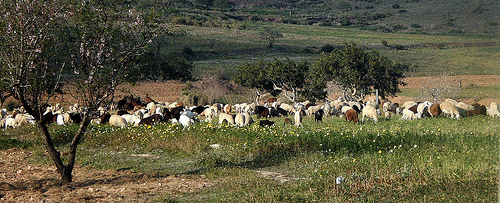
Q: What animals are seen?
A: Sheep.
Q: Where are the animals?
A: Field.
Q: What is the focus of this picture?
A: Animals.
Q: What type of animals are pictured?
A: Cattle.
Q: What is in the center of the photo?
A: Row of trees.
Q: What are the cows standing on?
A: Grass.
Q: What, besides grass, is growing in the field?
A: Flowers.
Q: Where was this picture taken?
A: In a field.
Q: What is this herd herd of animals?
A: Grass.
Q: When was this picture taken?
A: During the day hours.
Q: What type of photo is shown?
A: Panorama.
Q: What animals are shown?
A: Cows.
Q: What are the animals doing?
A: Eating.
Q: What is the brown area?
A: Dirt.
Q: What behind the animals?
A: Hills.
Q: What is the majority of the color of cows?
A: White.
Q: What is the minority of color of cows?
A: Brown.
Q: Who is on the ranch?
A: Cattle.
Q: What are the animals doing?
A: Grazing.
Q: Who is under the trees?
A: Cattle.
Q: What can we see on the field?
A: A herd of cattle.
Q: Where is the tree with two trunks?
A: On the left.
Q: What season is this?
A: Summer.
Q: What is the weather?
A: Sunny.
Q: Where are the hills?
A: Behind the cows.